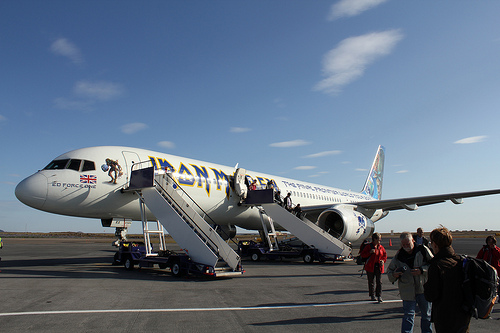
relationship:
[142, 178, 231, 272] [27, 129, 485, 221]
steps attached to plane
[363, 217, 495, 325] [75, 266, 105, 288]
people standing on road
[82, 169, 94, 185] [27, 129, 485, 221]
flag on plane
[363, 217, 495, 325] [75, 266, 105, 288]
people are on road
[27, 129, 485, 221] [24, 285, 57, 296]
plane on ground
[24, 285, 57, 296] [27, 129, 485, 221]
ground under plane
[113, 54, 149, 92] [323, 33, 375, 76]
sky has cloud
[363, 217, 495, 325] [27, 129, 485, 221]
people are ourside plane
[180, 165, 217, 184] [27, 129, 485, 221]
logo on plane